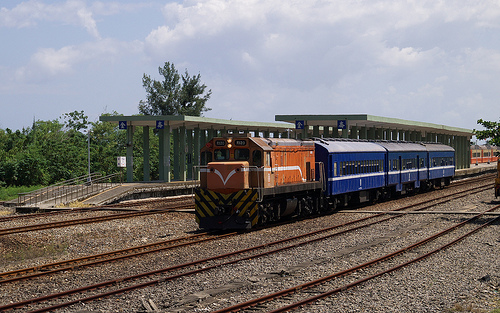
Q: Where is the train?
A: On the tracks.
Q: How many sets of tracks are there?
A: Four.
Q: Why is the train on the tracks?
A: So it can travel.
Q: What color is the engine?
A: Orange.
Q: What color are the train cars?
A: Blue.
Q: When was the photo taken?
A: Daytime.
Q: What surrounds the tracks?
A: Rocks.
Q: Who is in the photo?
A: Nobody.